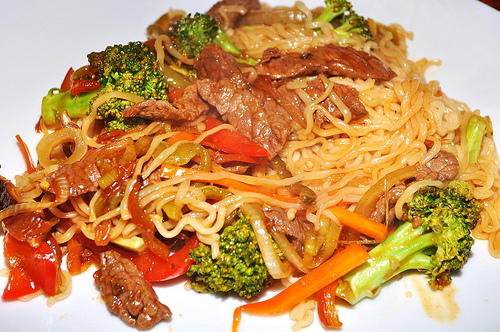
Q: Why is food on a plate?
A: To be eaten.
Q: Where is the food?
A: On white plate.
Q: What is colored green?
A: Broccoli.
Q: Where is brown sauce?
A: On the food.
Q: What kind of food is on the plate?
A: Asian.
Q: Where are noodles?
A: On plate.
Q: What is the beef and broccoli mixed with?
A: Lo mein.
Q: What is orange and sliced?
A: Carrots.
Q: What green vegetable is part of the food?
A: Broccoli.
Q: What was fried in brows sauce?
A: Onion.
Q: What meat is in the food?
A: Beef.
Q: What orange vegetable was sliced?
A: Carrot.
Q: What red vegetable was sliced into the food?
A: Red pepper.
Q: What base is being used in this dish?
A: Noodles.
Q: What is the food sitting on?
A: Plate.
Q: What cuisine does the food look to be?
A: Chinese.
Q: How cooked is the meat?
A: Well.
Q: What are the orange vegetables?
A: Carrots.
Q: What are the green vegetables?
A: Broccoli.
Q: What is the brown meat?
A: Beef.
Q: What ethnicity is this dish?
A: Asian.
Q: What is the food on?
A: Plate.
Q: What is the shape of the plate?
A: Round.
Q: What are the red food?
A: Peppers.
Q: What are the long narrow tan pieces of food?
A: Noodles.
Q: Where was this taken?
A: Restaurant.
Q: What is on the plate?
A: Food.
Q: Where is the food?
A: On the plate.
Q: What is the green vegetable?
A: Broccoli.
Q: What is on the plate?
A: Food.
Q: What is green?
A: Broccoli.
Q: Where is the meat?
A: On the plate.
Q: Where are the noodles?
A: On the plate.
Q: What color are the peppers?
A: Red.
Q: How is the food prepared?
A: Mixed together.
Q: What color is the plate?
A: White.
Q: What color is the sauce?
A: Brown.